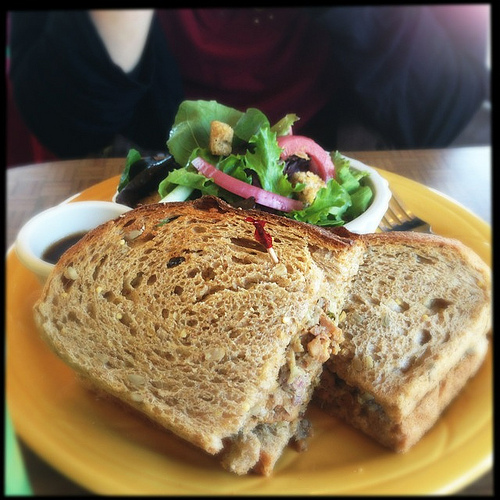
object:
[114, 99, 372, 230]
salad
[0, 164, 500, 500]
plate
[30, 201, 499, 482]
sandwich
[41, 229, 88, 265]
sauce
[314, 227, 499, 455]
bread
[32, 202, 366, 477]
bread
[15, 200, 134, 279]
dish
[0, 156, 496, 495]
table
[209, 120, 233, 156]
crouton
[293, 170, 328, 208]
crouton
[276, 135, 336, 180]
tomato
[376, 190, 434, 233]
fork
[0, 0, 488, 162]
person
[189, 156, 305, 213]
onion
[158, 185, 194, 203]
onion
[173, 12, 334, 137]
scarf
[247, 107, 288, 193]
lettuce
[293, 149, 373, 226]
lettuce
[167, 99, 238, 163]
lettuce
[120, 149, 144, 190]
lettuce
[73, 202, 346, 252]
crust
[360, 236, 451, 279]
crust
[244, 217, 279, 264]
toothpick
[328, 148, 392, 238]
bowl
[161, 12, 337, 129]
shirt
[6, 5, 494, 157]
sweater